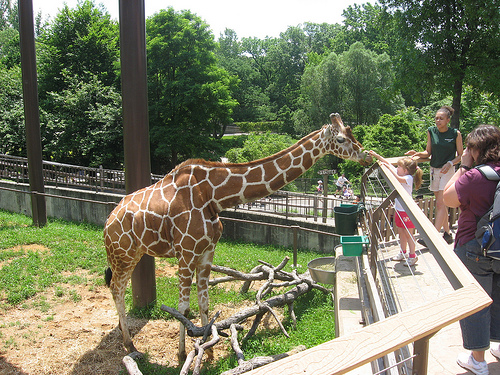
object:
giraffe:
[103, 111, 376, 353]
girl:
[366, 149, 421, 267]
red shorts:
[392, 208, 415, 228]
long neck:
[203, 128, 324, 219]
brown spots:
[160, 181, 180, 206]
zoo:
[0, 0, 500, 374]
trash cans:
[330, 204, 361, 237]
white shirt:
[394, 171, 418, 213]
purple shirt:
[453, 163, 500, 249]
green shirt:
[425, 125, 460, 169]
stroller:
[339, 185, 361, 203]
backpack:
[463, 164, 500, 276]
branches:
[158, 302, 195, 332]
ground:
[0, 210, 336, 374]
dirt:
[16, 300, 162, 374]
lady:
[440, 123, 500, 374]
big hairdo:
[462, 123, 500, 167]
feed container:
[331, 203, 365, 236]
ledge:
[357, 159, 478, 317]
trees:
[379, 0, 500, 127]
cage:
[0, 151, 492, 375]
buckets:
[339, 233, 370, 258]